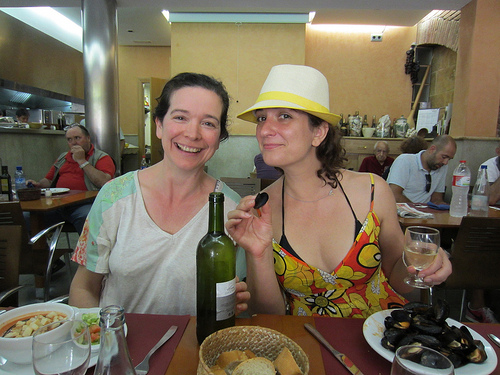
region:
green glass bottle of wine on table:
[191, 188, 240, 350]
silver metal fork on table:
[130, 323, 181, 373]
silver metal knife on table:
[298, 313, 368, 373]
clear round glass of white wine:
[399, 223, 443, 291]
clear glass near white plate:
[388, 342, 460, 373]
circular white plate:
[359, 306, 498, 373]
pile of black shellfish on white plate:
[379, 296, 489, 371]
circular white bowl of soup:
[1, 298, 80, 367]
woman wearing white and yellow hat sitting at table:
[222, 59, 454, 324]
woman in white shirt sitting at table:
[63, 68, 263, 328]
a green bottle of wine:
[199, 191, 237, 340]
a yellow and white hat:
[237, 63, 344, 130]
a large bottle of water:
[448, 156, 472, 218]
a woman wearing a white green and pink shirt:
[67, 72, 254, 322]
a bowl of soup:
[1, 301, 74, 362]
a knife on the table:
[301, 321, 363, 373]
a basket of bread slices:
[198, 327, 308, 373]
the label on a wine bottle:
[213, 276, 240, 324]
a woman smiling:
[153, 72, 229, 172]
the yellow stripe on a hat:
[251, 89, 336, 116]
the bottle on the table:
[190, 190, 247, 329]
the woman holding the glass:
[224, 85, 475, 333]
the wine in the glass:
[407, 245, 436, 270]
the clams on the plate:
[375, 305, 471, 363]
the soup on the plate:
[7, 308, 71, 348]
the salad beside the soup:
[64, 310, 110, 358]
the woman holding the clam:
[224, 181, 310, 313]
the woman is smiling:
[135, 55, 239, 189]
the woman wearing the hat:
[224, 61, 361, 196]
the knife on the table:
[302, 318, 360, 373]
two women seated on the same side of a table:
[0, 63, 497, 373]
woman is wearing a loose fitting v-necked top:
[72, 163, 246, 313]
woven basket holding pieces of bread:
[196, 323, 309, 374]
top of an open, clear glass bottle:
[94, 304, 133, 373]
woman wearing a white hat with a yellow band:
[237, 63, 341, 125]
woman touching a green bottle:
[195, 192, 250, 339]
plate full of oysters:
[364, 301, 496, 373]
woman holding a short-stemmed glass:
[400, 226, 451, 289]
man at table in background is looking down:
[385, 132, 498, 229]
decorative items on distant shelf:
[338, 53, 451, 140]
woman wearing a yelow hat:
[235, 63, 340, 120]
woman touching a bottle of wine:
[195, 190, 247, 343]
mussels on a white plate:
[382, 299, 487, 366]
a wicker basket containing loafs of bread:
[197, 326, 307, 373]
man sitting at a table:
[25, 123, 115, 275]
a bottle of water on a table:
[15, 165, 25, 190]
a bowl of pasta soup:
[0, 300, 78, 365]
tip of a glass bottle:
[96, 304, 131, 373]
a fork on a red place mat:
[130, 323, 176, 373]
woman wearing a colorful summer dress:
[272, 172, 405, 318]